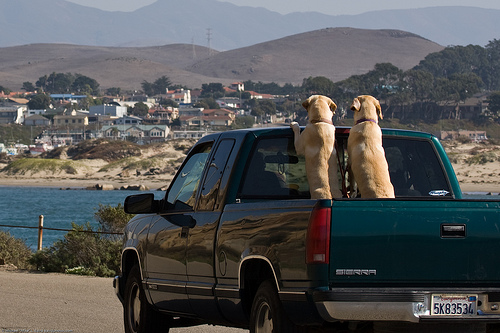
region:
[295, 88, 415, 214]
two dogs in the back of a sierra SUV trunck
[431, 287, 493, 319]
a California tag for a vehicle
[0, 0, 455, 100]
two sets of mountains in the background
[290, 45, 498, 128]
high green trees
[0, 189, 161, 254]
blue water separating two lands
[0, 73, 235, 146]
many houses on a small hill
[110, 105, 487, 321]
a drak green SUV sierra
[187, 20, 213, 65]
two electric pole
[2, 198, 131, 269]
green bushes along a road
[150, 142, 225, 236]
a glass door window slightly open.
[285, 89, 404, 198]
two dogs are standing in the back of a truck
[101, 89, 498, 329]
a dark green truck with two dogs in the back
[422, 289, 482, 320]
license plate on a truck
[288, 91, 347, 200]
a dog has it's front paws on the roof of a truck cab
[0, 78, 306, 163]
buildings on the side of a body of water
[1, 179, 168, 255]
water in front of a dark green truck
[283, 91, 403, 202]
two dogs are peering over a truck cab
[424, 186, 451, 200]
sticker on a truck window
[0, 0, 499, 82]
mountains behind a small town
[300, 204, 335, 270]
left back light on a truck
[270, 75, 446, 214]
two dogs in the back of truck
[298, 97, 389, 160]
dogs are wearing collars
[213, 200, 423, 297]
SIERRA is on the back of truck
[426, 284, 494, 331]
California is the license plate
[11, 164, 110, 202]
shoreline of water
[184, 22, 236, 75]
two power towers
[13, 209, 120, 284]
fence along the road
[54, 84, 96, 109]
roof is blue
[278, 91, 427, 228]
dogs standing in the back of truck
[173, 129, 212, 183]
driver's window is cracked open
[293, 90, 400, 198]
two dogs in back of truck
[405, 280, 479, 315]
license plate on back of truck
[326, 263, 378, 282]
sierra make on truck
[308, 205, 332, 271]
tail light on back of truck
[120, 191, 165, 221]
side mirror on truck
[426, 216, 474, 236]
back tailgate pull on truck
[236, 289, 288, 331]
back tire of truck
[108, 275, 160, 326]
front tire of truck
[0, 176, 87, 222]
body of blue water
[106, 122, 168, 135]
large house across water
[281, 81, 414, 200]
Two blonde labs in truck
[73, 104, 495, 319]
Green Sierra pickup trucks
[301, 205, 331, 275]
Red tail light on truck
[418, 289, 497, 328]
White licence plate on truck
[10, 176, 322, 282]
Body of water to the right of truck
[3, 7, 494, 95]
Mountain range in the distance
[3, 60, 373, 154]
Small village on hillside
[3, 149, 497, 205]
Sandy shore by the water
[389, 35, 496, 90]
Green trees across the river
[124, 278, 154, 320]
Silver hubcap on tire